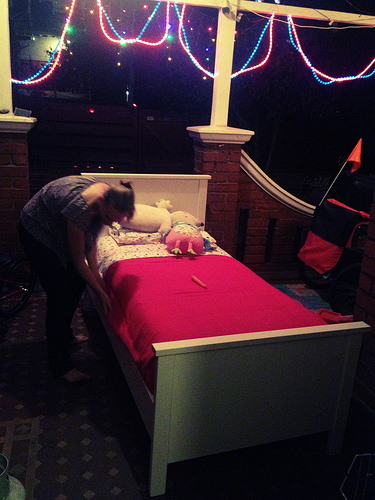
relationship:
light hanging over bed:
[98, 13, 132, 49] [84, 173, 352, 457]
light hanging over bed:
[47, 11, 85, 69] [84, 173, 352, 457]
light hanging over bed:
[293, 36, 374, 95] [84, 173, 352, 457]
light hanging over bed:
[176, 25, 204, 66] [84, 173, 352, 457]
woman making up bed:
[17, 164, 135, 375] [84, 173, 352, 457]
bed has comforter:
[84, 173, 352, 457] [118, 255, 277, 331]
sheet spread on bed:
[101, 232, 166, 257] [84, 173, 352, 457]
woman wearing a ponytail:
[17, 164, 135, 375] [126, 180, 133, 214]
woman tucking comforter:
[17, 164, 135, 375] [118, 255, 277, 331]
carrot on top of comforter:
[192, 275, 210, 290] [118, 255, 277, 331]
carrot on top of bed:
[192, 275, 210, 290] [84, 173, 352, 457]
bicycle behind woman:
[4, 256, 30, 320] [17, 164, 135, 375]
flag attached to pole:
[350, 142, 360, 172] [321, 162, 346, 200]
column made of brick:
[200, 142, 242, 252] [218, 185, 239, 195]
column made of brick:
[2, 134, 31, 262] [5, 166, 28, 179]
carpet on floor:
[8, 300, 118, 493] [1, 266, 374, 495]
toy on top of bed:
[162, 212, 209, 255] [84, 173, 352, 457]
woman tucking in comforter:
[17, 164, 135, 375] [118, 255, 277, 331]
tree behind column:
[247, 28, 315, 168] [200, 142, 242, 252]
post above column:
[211, 12, 233, 129] [200, 142, 242, 252]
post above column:
[3, 5, 14, 113] [2, 134, 31, 262]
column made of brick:
[200, 142, 242, 252] [205, 152, 228, 162]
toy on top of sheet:
[162, 212, 209, 255] [101, 232, 166, 257]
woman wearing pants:
[17, 164, 135, 375] [22, 237, 93, 369]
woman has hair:
[17, 164, 135, 375] [109, 184, 136, 211]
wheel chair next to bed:
[304, 202, 368, 307] [84, 173, 352, 457]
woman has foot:
[17, 164, 135, 375] [65, 370, 83, 382]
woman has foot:
[17, 164, 135, 375] [74, 334, 90, 346]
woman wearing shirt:
[17, 164, 135, 375] [28, 181, 85, 242]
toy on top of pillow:
[162, 212, 209, 255] [117, 232, 157, 244]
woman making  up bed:
[17, 164, 135, 375] [84, 173, 352, 457]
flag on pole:
[350, 142, 360, 172] [321, 162, 346, 200]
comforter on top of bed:
[118, 255, 277, 331] [84, 173, 352, 457]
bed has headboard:
[84, 173, 352, 457] [87, 175, 211, 217]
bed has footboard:
[84, 173, 352, 457] [164, 347, 348, 437]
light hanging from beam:
[176, 25, 204, 66] [200, 4, 373, 30]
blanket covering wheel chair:
[301, 201, 356, 276] [304, 202, 368, 307]